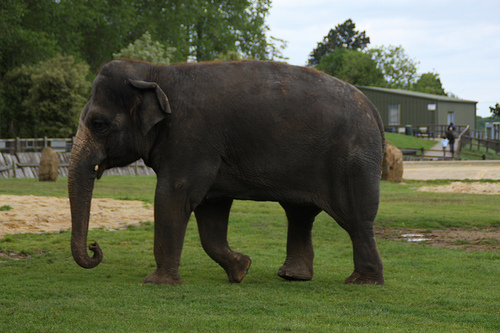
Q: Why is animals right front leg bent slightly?
A: It's walking.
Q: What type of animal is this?
A: Elephant.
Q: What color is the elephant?
A: Dark gray.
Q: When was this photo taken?
A: Daytime.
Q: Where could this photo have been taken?
A: Wildlife refuge.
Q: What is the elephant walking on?
A: Grass.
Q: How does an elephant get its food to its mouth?
A: With trunk.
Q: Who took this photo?
A: Photographer.